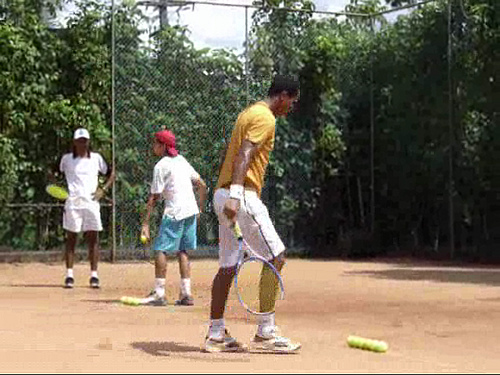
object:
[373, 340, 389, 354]
ball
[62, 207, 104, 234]
shorts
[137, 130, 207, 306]
boy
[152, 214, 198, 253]
shorts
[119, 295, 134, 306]
tennis ball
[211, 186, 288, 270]
shorts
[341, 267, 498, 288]
shadow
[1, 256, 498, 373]
court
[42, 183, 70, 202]
tennis racket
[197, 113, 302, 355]
playiing tennis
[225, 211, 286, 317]
racket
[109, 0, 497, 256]
fence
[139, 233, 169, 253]
tennis ball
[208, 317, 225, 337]
white sock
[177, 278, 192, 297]
white sock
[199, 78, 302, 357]
man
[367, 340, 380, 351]
balls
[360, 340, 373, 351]
balls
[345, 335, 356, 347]
ball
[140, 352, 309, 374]
floor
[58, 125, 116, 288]
man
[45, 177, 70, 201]
racket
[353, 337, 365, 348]
balls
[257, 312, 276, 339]
socks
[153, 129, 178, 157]
cap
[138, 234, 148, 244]
ball